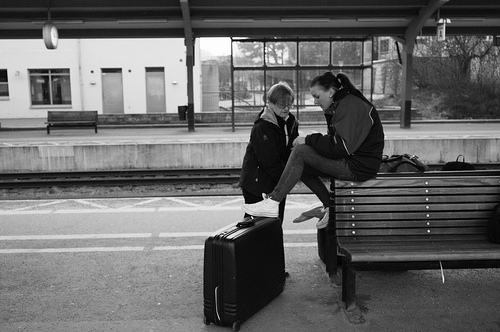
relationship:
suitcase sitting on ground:
[203, 214, 287, 330] [259, 305, 307, 326]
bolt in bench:
[321, 159, 486, 284] [337, 179, 498, 266]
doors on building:
[101, 64, 167, 114] [3, 36, 200, 116]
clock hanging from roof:
[40, 25, 60, 51] [63, 19, 178, 37]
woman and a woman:
[244, 82, 301, 215] [290, 53, 380, 222]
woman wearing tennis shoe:
[240, 53, 386, 222] [241, 191, 287, 220]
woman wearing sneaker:
[240, 53, 386, 222] [316, 205, 330, 228]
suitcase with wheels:
[178, 208, 302, 327] [168, 312, 256, 330]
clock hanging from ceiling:
[43, 22, 57, 53] [1, 1, 498, 53]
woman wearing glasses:
[240, 53, 386, 222] [269, 100, 296, 107]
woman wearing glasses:
[239, 82, 300, 276] [269, 100, 296, 107]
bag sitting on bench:
[380, 149, 422, 176] [325, 167, 499, 309]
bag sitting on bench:
[432, 154, 476, 174] [325, 167, 499, 309]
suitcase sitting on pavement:
[203, 214, 287, 330] [0, 118, 499, 330]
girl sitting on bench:
[283, 55, 388, 206] [305, 150, 497, 332]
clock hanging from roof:
[42, 17, 57, 47] [2, 3, 499, 33]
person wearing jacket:
[231, 91, 307, 241] [296, 96, 388, 161]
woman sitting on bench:
[240, 53, 386, 222] [325, 167, 499, 309]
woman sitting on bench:
[240, 53, 386, 222] [318, 170, 499, 302]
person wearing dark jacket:
[238, 77, 303, 229] [238, 104, 299, 227]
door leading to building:
[98, 59, 213, 141] [36, 39, 243, 127]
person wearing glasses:
[231, 76, 300, 288] [271, 97, 296, 112]